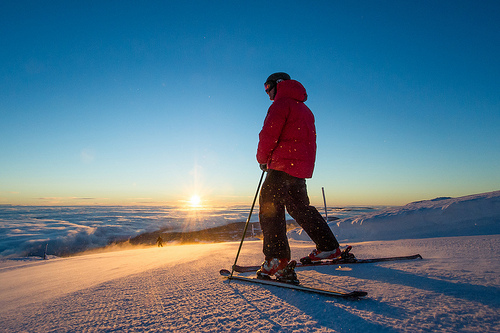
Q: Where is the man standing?
A: Top of a snow covered hill.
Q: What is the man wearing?
A: Ski's.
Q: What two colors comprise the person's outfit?
A: Red and black.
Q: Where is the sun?
A: Middle of photo.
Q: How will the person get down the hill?
A: Ski.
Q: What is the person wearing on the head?
A: Hat.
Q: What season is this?
A: Winter.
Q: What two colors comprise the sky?
A: Blue and yellow.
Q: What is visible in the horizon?
A: Sunrise.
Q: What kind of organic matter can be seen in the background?
A: Mountain.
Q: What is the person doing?
A: Skiing.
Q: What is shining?
A: Sun.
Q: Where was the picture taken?
A: Ski slope.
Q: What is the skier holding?
A: Ski pole.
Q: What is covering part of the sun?
A: Clouds.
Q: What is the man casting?
A: Shadow.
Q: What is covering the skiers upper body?
A: Coat.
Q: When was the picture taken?
A: Winter.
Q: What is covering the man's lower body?
A: Pants.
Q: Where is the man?
A: On a ski slope.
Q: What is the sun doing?
A: Setting.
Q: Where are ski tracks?
A: In the snow.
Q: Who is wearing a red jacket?
A: The skier.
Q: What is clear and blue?
A: Sky.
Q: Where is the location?
A: Hillside.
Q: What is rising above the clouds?
A: The sun.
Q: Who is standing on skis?
A: A man.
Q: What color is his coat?
A: Red.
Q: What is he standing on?
A: Skis.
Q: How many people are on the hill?
A: Two.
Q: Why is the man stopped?
A: He is waiting to ski.